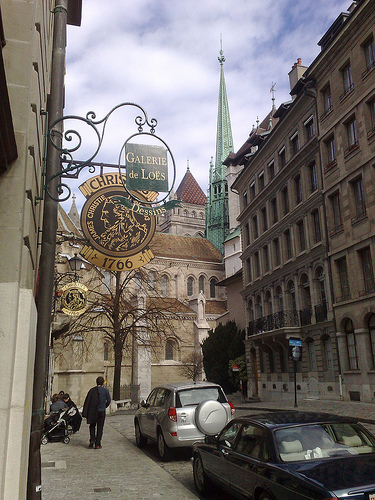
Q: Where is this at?
A: Geneva, switzerland.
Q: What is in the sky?
A: Clouds.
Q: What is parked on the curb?
A: Vehicles.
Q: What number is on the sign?
A: 1766.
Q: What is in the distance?
A: Towers.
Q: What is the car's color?
A: Black.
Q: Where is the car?
A: Next to sidewalk.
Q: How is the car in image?
A: Parked on street.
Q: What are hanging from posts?
A: Store signs.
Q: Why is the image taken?
A: Remembrance.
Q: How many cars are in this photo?
A: Two.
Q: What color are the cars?
A: Silver and black.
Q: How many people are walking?
A: One.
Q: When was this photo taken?
A: Outside, during the daytime.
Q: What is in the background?
A: Lots of buildings.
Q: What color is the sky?
A: Blue.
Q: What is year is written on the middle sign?
A: 1766.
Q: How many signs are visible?
A: Three.